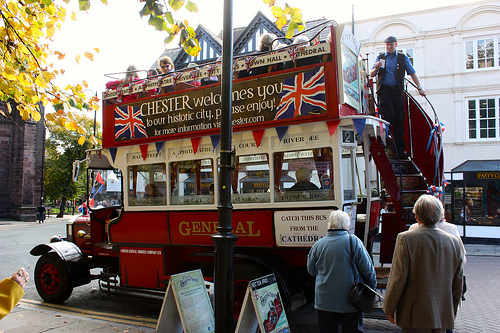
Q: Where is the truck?
A: On the road.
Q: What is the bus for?
A: Tours.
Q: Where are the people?
A: On the sidewalk.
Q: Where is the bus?
A: In britain.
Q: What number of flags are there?
A: Two.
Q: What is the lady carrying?
A: Purse.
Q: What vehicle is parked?
A: Truck.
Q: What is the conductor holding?
A: Cup.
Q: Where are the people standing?
A: Sidewalk.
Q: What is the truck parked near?
A: Curb.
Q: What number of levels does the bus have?
A: Two.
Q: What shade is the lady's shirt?
A: Blue.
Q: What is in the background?
A: Building.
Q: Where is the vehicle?
A: Street.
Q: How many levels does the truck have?
A: Two.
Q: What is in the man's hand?
A: A cup.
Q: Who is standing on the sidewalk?
A: A man and lady.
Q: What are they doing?
A: Reading the signs on the truck.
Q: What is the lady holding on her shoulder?
A: Purse.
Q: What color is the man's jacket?
A: Brown.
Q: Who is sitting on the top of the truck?
A: A group of people.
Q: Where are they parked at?
A: On the side of the street.